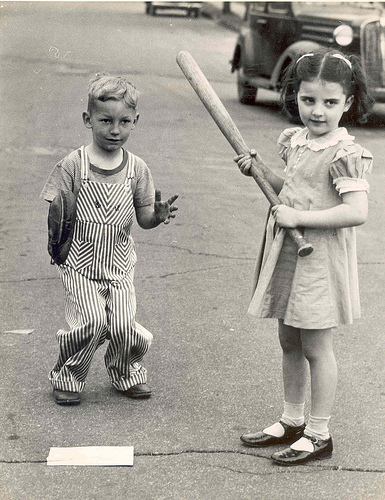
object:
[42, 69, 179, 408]
boy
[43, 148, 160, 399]
overalls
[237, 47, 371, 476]
girl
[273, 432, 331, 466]
shoes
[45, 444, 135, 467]
paper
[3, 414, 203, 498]
pavement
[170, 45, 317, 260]
bat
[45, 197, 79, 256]
mitt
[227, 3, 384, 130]
truck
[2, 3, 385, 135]
background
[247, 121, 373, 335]
dress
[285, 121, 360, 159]
collar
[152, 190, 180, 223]
hand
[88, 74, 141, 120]
hair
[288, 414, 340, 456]
socks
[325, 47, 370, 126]
pigtails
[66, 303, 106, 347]
knees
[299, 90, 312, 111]
eyes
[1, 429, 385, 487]
crack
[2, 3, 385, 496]
street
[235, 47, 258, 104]
tires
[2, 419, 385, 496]
ground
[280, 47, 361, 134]
hair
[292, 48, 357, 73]
barrettes